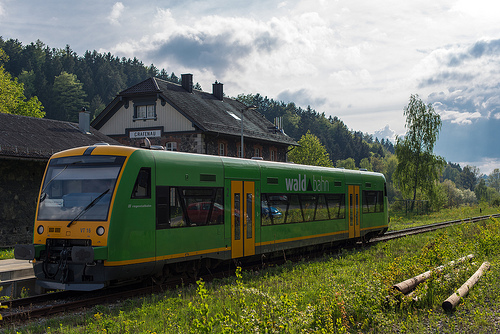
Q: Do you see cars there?
A: No, there are no cars.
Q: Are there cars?
A: No, there are no cars.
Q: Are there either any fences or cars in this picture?
A: No, there are no cars or fences.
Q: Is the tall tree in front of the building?
A: No, the tree is behind the building.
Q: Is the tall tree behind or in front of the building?
A: The tree is behind the building.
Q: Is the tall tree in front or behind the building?
A: The tree is behind the building.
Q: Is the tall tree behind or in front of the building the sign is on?
A: The tree is behind the building.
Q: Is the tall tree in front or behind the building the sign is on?
A: The tree is behind the building.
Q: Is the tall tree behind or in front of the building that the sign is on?
A: The tree is behind the building.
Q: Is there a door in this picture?
A: Yes, there are doors.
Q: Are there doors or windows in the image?
A: Yes, there are doors.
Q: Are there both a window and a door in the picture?
A: Yes, there are both a door and a window.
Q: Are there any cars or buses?
A: No, there are no cars or buses.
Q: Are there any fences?
A: No, there are no fences.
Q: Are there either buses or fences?
A: No, there are no fences or buses.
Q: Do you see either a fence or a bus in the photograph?
A: No, there are no fences or buses.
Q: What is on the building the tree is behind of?
A: The sign is on the building.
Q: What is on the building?
A: The sign is on the building.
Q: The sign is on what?
A: The sign is on the building.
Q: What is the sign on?
A: The sign is on the building.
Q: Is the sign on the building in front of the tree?
A: Yes, the sign is on the building.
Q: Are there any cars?
A: No, there are no cars.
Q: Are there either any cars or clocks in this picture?
A: No, there are no cars or clocks.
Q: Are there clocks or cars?
A: No, there are no cars or clocks.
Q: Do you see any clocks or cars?
A: No, there are no cars or clocks.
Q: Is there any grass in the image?
A: Yes, there is grass.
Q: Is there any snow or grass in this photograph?
A: Yes, there is grass.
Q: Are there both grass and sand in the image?
A: No, there is grass but no sand.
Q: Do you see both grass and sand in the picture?
A: No, there is grass but no sand.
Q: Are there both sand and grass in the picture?
A: No, there is grass but no sand.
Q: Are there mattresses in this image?
A: No, there are no mattresses.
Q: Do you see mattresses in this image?
A: No, there are no mattresses.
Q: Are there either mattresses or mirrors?
A: No, there are no mattresses or mirrors.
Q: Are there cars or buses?
A: No, there are no cars or buses.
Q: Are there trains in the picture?
A: Yes, there is a train.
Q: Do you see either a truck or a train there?
A: Yes, there is a train.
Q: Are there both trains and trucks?
A: No, there is a train but no trucks.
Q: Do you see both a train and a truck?
A: No, there is a train but no trucks.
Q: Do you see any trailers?
A: No, there are no trailers.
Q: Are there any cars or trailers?
A: No, there are no trailers or cars.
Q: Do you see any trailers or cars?
A: No, there are no trailers or cars.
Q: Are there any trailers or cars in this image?
A: No, there are no trailers or cars.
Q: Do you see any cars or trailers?
A: No, there are no trailers or cars.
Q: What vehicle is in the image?
A: The vehicle is a train.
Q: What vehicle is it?
A: The vehicle is a train.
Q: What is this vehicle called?
A: This is a train.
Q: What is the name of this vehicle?
A: This is a train.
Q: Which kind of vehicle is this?
A: This is a train.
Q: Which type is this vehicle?
A: This is a train.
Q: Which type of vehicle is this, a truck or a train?
A: This is a train.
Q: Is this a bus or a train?
A: This is a train.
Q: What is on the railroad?
A: The train is on the railroad.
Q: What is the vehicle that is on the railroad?
A: The vehicle is a train.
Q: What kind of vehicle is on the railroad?
A: The vehicle is a train.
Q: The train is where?
A: The train is on the railroad.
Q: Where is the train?
A: The train is on the railroad.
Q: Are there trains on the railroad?
A: Yes, there is a train on the railroad.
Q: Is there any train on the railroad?
A: Yes, there is a train on the railroad.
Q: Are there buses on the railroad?
A: No, there is a train on the railroad.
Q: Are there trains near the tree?
A: Yes, there is a train near the tree.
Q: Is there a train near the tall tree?
A: Yes, there is a train near the tree.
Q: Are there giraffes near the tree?
A: No, there is a train near the tree.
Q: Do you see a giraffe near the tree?
A: No, there is a train near the tree.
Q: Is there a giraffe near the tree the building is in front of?
A: No, there is a train near the tree.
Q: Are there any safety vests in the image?
A: No, there are no safety vests.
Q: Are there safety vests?
A: No, there are no safety vests.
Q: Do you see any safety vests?
A: No, there are no safety vests.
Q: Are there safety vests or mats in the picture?
A: No, there are no safety vests or mats.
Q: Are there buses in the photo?
A: No, there are no buses.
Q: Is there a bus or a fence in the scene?
A: No, there are no buses or fences.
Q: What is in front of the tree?
A: The building is in front of the tree.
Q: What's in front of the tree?
A: The building is in front of the tree.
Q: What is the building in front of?
A: The building is in front of the tree.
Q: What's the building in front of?
A: The building is in front of the tree.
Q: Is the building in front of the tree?
A: Yes, the building is in front of the tree.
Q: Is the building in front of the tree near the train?
A: Yes, the building is in front of the tree.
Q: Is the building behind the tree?
A: No, the building is in front of the tree.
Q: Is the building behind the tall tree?
A: No, the building is in front of the tree.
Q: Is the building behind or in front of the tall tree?
A: The building is in front of the tree.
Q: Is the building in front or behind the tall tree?
A: The building is in front of the tree.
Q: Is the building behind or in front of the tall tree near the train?
A: The building is in front of the tree.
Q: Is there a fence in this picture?
A: No, there are no fences.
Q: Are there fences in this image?
A: No, there are no fences.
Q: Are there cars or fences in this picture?
A: No, there are no fences or cars.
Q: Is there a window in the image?
A: Yes, there is a window.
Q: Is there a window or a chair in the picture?
A: Yes, there is a window.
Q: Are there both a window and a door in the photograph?
A: Yes, there are both a window and a door.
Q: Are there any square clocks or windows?
A: Yes, there is a square window.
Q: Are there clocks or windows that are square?
A: Yes, the window is square.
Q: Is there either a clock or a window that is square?
A: Yes, the window is square.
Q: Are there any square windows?
A: Yes, there is a square window.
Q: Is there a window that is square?
A: Yes, there is a window that is square.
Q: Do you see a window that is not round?
A: Yes, there is a square window.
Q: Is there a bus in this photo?
A: No, there are no buses.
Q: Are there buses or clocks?
A: No, there are no buses or clocks.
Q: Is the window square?
A: Yes, the window is square.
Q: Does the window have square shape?
A: Yes, the window is square.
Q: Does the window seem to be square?
A: Yes, the window is square.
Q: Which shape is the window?
A: The window is square.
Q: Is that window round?
A: No, the window is square.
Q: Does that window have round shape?
A: No, the window is square.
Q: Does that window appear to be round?
A: No, the window is square.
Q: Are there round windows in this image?
A: No, there is a window but it is square.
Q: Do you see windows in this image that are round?
A: No, there is a window but it is square.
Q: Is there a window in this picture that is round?
A: No, there is a window but it is square.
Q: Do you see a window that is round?
A: No, there is a window but it is square.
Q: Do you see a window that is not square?
A: No, there is a window but it is square.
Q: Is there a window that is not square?
A: No, there is a window but it is square.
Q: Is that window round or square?
A: The window is square.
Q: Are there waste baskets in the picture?
A: No, there are no waste baskets.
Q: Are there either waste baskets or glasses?
A: No, there are no waste baskets or glasses.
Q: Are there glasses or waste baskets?
A: No, there are no waste baskets or glasses.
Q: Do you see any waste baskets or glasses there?
A: No, there are no waste baskets or glasses.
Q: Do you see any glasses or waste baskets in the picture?
A: No, there are no waste baskets or glasses.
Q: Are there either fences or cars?
A: No, there are no fences or cars.